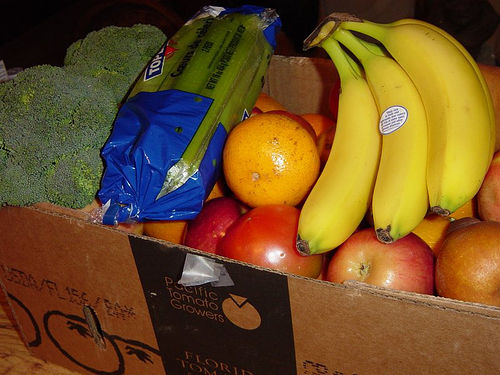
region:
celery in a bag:
[137, 16, 228, 218]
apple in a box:
[341, 240, 437, 286]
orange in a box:
[231, 122, 311, 202]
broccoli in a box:
[15, 71, 108, 175]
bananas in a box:
[318, 13, 484, 233]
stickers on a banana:
[373, 101, 413, 141]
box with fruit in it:
[24, 25, 499, 332]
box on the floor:
[3, 201, 437, 371]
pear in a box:
[440, 207, 499, 300]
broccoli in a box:
[56, 18, 183, 98]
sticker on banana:
[381, 104, 407, 136]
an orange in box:
[225, 110, 311, 207]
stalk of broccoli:
[1, 67, 105, 204]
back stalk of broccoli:
[68, 23, 168, 82]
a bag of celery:
[100, 17, 280, 232]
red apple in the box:
[185, 198, 258, 259]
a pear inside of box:
[433, 221, 498, 300]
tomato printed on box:
[225, 284, 257, 333]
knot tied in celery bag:
[102, 183, 148, 226]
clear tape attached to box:
[166, 249, 242, 298]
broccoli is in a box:
[13, 49, 236, 176]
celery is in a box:
[113, 58, 328, 233]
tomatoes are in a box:
[195, 187, 307, 288]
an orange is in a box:
[207, 128, 374, 264]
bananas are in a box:
[286, 39, 492, 250]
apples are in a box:
[330, 212, 497, 346]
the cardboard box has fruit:
[34, 223, 269, 373]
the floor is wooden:
[2, 342, 37, 371]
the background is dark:
[12, 10, 113, 87]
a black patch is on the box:
[112, 241, 313, 370]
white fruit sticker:
[376, 103, 409, 135]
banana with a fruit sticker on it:
[331, 23, 433, 246]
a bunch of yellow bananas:
[293, 7, 494, 258]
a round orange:
[218, 110, 323, 207]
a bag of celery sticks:
[96, 5, 284, 225]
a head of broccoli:
[2, 59, 119, 214]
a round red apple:
[323, 223, 438, 298]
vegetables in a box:
[3, 0, 280, 234]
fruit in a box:
[113, 3, 498, 318]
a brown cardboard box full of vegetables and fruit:
[2, 2, 495, 373]